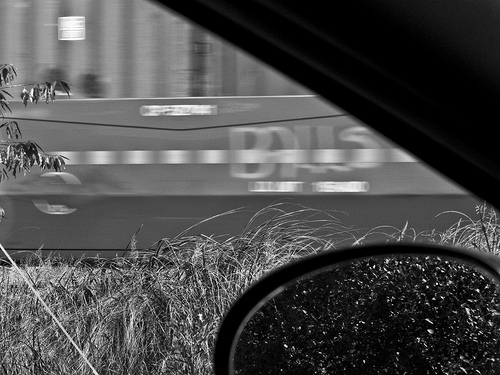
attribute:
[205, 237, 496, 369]
black object — circular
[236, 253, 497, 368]
mirror — outline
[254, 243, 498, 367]
mirror — rear view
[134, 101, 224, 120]
writing — white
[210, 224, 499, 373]
mirror — wet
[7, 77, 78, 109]
tree branch — small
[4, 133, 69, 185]
tree branch — small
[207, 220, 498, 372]
rearview mirror — black, glass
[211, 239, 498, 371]
mirror — rear view, wet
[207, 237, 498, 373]
frame — black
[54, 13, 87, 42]
sign — white, square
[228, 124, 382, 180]
graffiti — white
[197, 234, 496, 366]
object — black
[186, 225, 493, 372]
outline — black